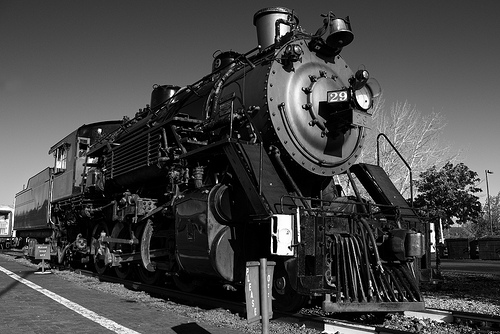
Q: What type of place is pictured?
A: It is a railroad.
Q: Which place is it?
A: It is a railroad.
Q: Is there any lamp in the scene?
A: Yes, there is a lamp.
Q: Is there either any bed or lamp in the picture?
A: Yes, there is a lamp.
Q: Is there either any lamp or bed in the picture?
A: Yes, there is a lamp.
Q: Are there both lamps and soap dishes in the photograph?
A: No, there is a lamp but no soap dishes.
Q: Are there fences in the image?
A: No, there are no fences.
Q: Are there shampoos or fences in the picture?
A: No, there are no fences or shampoos.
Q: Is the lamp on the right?
A: Yes, the lamp is on the right of the image.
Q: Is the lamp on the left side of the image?
A: No, the lamp is on the right of the image.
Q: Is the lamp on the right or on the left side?
A: The lamp is on the right of the image.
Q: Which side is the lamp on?
A: The lamp is on the right of the image.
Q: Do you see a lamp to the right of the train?
A: Yes, there is a lamp to the right of the train.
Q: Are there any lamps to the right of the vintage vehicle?
A: Yes, there is a lamp to the right of the train.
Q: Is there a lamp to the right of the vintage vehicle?
A: Yes, there is a lamp to the right of the train.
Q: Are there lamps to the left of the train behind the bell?
A: No, the lamp is to the right of the train.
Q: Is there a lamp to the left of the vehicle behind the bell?
A: No, the lamp is to the right of the train.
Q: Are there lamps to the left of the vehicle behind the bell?
A: No, the lamp is to the right of the train.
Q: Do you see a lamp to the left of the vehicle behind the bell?
A: No, the lamp is to the right of the train.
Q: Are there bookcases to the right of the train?
A: No, there is a lamp to the right of the train.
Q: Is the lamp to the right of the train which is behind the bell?
A: Yes, the lamp is to the right of the train.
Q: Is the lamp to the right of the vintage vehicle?
A: Yes, the lamp is to the right of the train.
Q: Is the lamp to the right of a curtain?
A: No, the lamp is to the right of the train.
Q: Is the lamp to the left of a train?
A: No, the lamp is to the right of a train.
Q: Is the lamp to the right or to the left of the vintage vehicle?
A: The lamp is to the right of the train.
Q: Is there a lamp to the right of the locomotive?
A: Yes, there is a lamp to the right of the locomotive.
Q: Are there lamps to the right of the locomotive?
A: Yes, there is a lamp to the right of the locomotive.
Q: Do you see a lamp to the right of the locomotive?
A: Yes, there is a lamp to the right of the locomotive.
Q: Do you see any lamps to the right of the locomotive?
A: Yes, there is a lamp to the right of the locomotive.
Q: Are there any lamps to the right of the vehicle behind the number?
A: Yes, there is a lamp to the right of the locomotive.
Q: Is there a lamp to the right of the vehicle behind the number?
A: Yes, there is a lamp to the right of the locomotive.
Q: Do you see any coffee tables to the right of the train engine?
A: No, there is a lamp to the right of the train engine.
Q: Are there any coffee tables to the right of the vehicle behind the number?
A: No, there is a lamp to the right of the train engine.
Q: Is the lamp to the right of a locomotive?
A: Yes, the lamp is to the right of a locomotive.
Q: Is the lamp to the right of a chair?
A: No, the lamp is to the right of a locomotive.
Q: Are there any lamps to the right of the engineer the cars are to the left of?
A: Yes, there is a lamp to the right of the engineer.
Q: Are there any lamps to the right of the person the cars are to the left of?
A: Yes, there is a lamp to the right of the engineer.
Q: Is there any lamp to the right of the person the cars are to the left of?
A: Yes, there is a lamp to the right of the engineer.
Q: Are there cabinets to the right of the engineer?
A: No, there is a lamp to the right of the engineer.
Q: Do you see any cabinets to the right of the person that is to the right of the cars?
A: No, there is a lamp to the right of the engineer.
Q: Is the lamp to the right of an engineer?
A: Yes, the lamp is to the right of an engineer.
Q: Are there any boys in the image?
A: No, there are no boys.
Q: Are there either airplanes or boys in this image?
A: No, there are no boys or airplanes.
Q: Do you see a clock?
A: No, there are no clocks.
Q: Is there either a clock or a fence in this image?
A: No, there are no clocks or fences.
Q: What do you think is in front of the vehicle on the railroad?
A: The number is in front of the engine.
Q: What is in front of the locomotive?
A: The number is in front of the engine.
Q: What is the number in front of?
A: The number is in front of the locomotive.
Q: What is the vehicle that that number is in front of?
A: The vehicle is a locomotive.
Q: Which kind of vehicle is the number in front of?
A: The number is in front of the engine.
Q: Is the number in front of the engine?
A: Yes, the number is in front of the engine.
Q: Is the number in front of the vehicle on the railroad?
A: Yes, the number is in front of the engine.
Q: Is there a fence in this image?
A: No, there are no fences.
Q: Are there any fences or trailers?
A: No, there are no fences or trailers.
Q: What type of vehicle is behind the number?
A: The vehicle is a locomotive.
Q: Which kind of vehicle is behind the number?
A: The vehicle is a locomotive.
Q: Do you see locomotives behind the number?
A: Yes, there is a locomotive behind the number.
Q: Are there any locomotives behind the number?
A: Yes, there is a locomotive behind the number.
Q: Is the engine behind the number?
A: Yes, the engine is behind the number.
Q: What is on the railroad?
A: The engine is on the railroad.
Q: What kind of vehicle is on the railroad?
A: The vehicle is a locomotive.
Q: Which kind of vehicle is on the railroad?
A: The vehicle is a locomotive.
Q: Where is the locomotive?
A: The locomotive is on the railroad.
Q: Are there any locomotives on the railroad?
A: Yes, there is a locomotive on the railroad.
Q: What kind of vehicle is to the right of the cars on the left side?
A: The vehicle is a locomotive.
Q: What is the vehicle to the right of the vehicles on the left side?
A: The vehicle is a locomotive.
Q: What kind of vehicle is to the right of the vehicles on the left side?
A: The vehicle is a locomotive.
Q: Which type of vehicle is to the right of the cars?
A: The vehicle is a locomotive.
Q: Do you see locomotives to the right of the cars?
A: Yes, there is a locomotive to the right of the cars.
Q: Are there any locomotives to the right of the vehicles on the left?
A: Yes, there is a locomotive to the right of the cars.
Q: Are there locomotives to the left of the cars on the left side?
A: No, the locomotive is to the right of the cars.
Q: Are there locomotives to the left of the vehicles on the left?
A: No, the locomotive is to the right of the cars.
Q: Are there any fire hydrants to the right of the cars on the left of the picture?
A: No, there is a locomotive to the right of the cars.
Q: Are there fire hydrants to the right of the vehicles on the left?
A: No, there is a locomotive to the right of the cars.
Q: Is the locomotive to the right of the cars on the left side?
A: Yes, the locomotive is to the right of the cars.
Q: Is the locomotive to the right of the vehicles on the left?
A: Yes, the locomotive is to the right of the cars.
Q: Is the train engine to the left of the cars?
A: No, the train engine is to the right of the cars.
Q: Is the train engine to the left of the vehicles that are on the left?
A: No, the train engine is to the right of the cars.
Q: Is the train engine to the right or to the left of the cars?
A: The train engine is to the right of the cars.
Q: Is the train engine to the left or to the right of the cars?
A: The train engine is to the right of the cars.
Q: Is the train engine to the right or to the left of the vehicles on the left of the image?
A: The train engine is to the right of the cars.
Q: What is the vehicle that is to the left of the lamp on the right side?
A: The vehicle is a locomotive.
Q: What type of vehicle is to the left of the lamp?
A: The vehicle is a locomotive.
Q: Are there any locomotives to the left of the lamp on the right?
A: Yes, there is a locomotive to the left of the lamp.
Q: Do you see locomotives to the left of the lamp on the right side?
A: Yes, there is a locomotive to the left of the lamp.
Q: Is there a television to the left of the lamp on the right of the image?
A: No, there is a locomotive to the left of the lamp.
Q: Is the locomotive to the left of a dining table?
A: No, the locomotive is to the left of a lamp.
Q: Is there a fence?
A: No, there are no fences.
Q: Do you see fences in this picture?
A: No, there are no fences.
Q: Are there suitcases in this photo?
A: No, there are no suitcases.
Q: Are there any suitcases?
A: No, there are no suitcases.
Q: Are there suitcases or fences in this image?
A: No, there are no suitcases or fences.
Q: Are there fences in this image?
A: No, there are no fences.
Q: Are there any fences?
A: No, there are no fences.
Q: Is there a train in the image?
A: Yes, there is a train.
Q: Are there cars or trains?
A: Yes, there is a train.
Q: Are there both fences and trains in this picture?
A: No, there is a train but no fences.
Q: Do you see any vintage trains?
A: Yes, there is a vintage train.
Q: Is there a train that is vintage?
A: Yes, there is a train that is vintage.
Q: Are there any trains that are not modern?
A: Yes, there is a vintage train.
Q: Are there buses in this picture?
A: No, there are no buses.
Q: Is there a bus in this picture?
A: No, there are no buses.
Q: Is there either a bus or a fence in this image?
A: No, there are no buses or fences.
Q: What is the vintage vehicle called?
A: The vehicle is a train.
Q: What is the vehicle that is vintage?
A: The vehicle is a train.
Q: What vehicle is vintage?
A: The vehicle is a train.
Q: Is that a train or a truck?
A: That is a train.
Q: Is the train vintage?
A: Yes, the train is vintage.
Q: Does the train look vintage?
A: Yes, the train is vintage.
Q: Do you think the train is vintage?
A: Yes, the train is vintage.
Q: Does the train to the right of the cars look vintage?
A: Yes, the train is vintage.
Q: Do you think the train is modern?
A: No, the train is vintage.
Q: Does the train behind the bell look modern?
A: No, the train is vintage.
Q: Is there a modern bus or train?
A: No, there is a train but it is vintage.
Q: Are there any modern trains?
A: No, there is a train but it is vintage.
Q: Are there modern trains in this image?
A: No, there is a train but it is vintage.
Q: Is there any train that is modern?
A: No, there is a train but it is vintage.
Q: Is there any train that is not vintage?
A: No, there is a train but it is vintage.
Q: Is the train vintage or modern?
A: The train is vintage.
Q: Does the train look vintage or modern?
A: The train is vintage.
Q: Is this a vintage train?
A: Yes, this is a vintage train.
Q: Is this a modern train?
A: No, this is a vintage train.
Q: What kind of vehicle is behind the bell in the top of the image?
A: The vehicle is a train.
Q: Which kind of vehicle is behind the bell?
A: The vehicle is a train.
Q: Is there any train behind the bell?
A: Yes, there is a train behind the bell.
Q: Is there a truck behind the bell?
A: No, there is a train behind the bell.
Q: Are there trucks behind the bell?
A: No, there is a train behind the bell.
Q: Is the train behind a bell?
A: Yes, the train is behind a bell.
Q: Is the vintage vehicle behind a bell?
A: Yes, the train is behind a bell.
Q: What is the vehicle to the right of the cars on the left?
A: The vehicle is a train.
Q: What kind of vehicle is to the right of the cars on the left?
A: The vehicle is a train.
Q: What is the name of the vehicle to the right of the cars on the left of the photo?
A: The vehicle is a train.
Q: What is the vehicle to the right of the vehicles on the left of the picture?
A: The vehicle is a train.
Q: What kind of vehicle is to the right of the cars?
A: The vehicle is a train.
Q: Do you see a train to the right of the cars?
A: Yes, there is a train to the right of the cars.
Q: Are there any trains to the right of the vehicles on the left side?
A: Yes, there is a train to the right of the cars.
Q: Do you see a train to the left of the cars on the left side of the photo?
A: No, the train is to the right of the cars.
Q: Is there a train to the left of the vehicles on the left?
A: No, the train is to the right of the cars.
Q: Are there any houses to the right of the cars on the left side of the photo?
A: No, there is a train to the right of the cars.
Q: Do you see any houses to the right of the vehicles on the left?
A: No, there is a train to the right of the cars.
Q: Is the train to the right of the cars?
A: Yes, the train is to the right of the cars.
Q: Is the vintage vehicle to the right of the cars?
A: Yes, the train is to the right of the cars.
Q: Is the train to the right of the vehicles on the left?
A: Yes, the train is to the right of the cars.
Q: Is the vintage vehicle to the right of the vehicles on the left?
A: Yes, the train is to the right of the cars.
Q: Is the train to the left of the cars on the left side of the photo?
A: No, the train is to the right of the cars.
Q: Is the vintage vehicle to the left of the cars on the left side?
A: No, the train is to the right of the cars.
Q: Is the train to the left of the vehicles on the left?
A: No, the train is to the right of the cars.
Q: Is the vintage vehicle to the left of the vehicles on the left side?
A: No, the train is to the right of the cars.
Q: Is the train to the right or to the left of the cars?
A: The train is to the right of the cars.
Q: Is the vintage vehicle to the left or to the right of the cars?
A: The train is to the right of the cars.